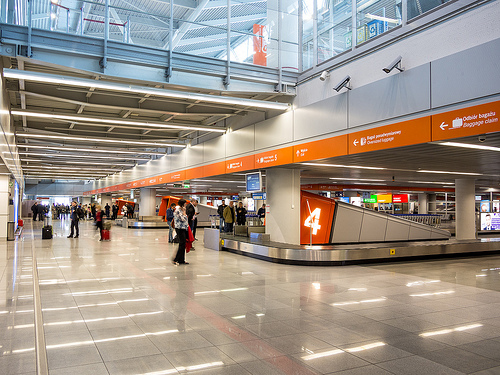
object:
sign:
[301, 194, 336, 247]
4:
[304, 207, 322, 235]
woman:
[170, 197, 193, 267]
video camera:
[332, 75, 352, 92]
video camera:
[380, 56, 405, 74]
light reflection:
[192, 282, 252, 300]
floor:
[0, 208, 499, 372]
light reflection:
[67, 281, 146, 300]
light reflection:
[328, 288, 391, 317]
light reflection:
[229, 307, 270, 326]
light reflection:
[298, 334, 386, 367]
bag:
[41, 225, 53, 239]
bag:
[100, 228, 111, 240]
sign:
[361, 193, 379, 205]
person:
[67, 199, 84, 239]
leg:
[67, 219, 74, 239]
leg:
[73, 221, 80, 239]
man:
[216, 198, 228, 228]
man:
[224, 201, 236, 233]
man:
[235, 201, 248, 226]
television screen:
[244, 172, 265, 193]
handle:
[42, 215, 52, 228]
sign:
[429, 106, 499, 135]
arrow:
[439, 121, 448, 130]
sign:
[343, 115, 436, 152]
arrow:
[353, 138, 359, 147]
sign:
[256, 154, 279, 163]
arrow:
[256, 157, 262, 167]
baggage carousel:
[214, 154, 499, 263]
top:
[172, 207, 193, 232]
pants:
[172, 227, 189, 266]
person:
[93, 203, 105, 242]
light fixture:
[3, 62, 295, 114]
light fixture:
[13, 130, 188, 153]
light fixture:
[13, 143, 171, 159]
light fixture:
[19, 154, 150, 170]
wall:
[294, 2, 500, 147]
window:
[3, 1, 298, 72]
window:
[302, 2, 436, 65]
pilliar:
[262, 164, 303, 247]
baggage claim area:
[14, 106, 498, 362]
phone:
[181, 205, 187, 211]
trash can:
[7, 221, 14, 243]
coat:
[181, 225, 197, 253]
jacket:
[222, 205, 237, 225]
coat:
[236, 206, 247, 223]